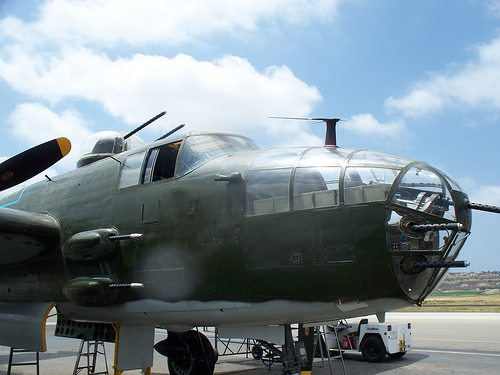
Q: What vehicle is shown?
A: Plane.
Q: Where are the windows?
A: On the plane.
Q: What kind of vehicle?
A: Plane.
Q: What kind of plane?
A: Bomber.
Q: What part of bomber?
A: Turret.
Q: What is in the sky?
A: Clouds.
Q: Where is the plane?
A: Runway.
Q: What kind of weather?
A: Mostly sunny.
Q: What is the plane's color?
A: Gray.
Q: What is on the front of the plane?
A: Glass.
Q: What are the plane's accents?
A: Yellow.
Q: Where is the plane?
A: On the ground.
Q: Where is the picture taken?
A: Airport.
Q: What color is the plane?
A: Green.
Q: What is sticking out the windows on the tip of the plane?
A: Guns.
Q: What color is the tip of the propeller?
A: Yellow.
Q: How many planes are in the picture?
A: One.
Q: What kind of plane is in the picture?
A: Military.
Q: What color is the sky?
A: Blue.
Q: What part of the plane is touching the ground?
A: Wheels.